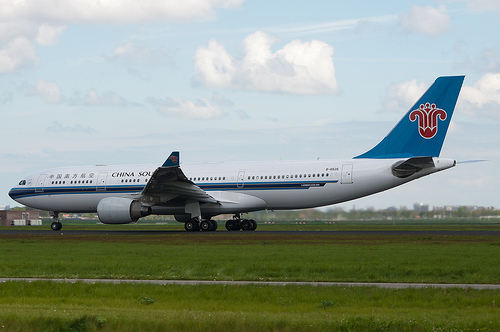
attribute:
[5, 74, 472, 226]
plane — white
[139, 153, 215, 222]
wing — blue